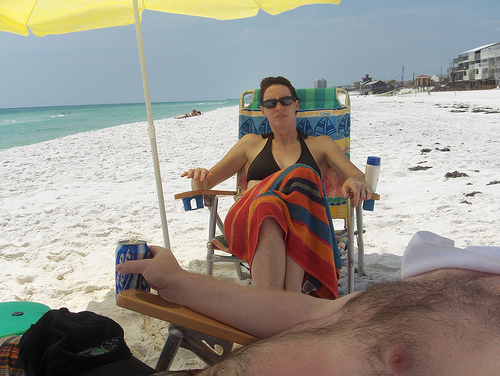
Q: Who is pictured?
A: Man and woman.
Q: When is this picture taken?
A: During vacation.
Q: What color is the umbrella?
A: Yellow.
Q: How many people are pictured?
A: Two.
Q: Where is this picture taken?
A: Beach.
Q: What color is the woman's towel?
A: Orange, red, and blue.